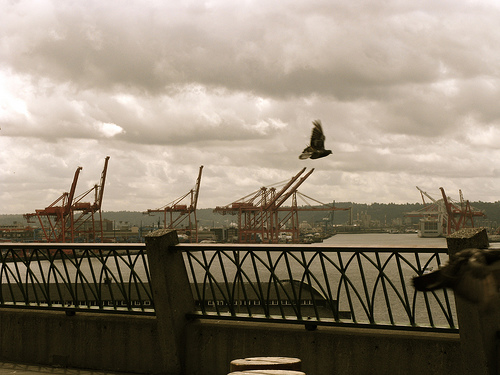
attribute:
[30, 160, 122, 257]
crane — large, orange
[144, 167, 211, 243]
crane — large, orange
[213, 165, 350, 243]
crane — large, orange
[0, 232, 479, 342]
wall — concrete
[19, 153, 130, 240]
equipment — orange, crane-type, construction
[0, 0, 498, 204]
sky — cloudy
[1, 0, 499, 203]
clouds — grey, dark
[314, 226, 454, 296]
water — large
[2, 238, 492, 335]
railing — metal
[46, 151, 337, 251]
cranes — large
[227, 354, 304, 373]
table — plastic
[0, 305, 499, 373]
wall — concrete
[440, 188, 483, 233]
crane — orange, large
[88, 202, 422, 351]
machines — industrial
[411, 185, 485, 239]
industrial machine — distant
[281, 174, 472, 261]
boat — lengthy, distant